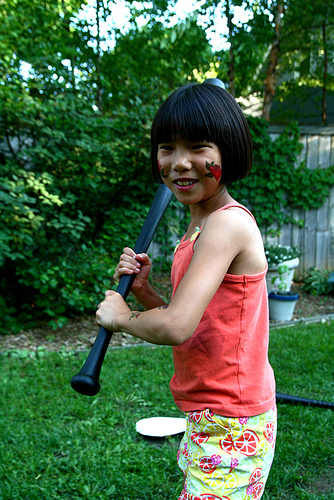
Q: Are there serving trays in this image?
A: No, there are no serving trays.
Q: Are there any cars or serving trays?
A: No, there are no serving trays or cars.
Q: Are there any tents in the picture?
A: No, there are no tents.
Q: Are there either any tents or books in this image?
A: No, there are no tents or books.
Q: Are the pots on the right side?
A: Yes, the pots are on the right of the image.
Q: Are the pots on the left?
A: No, the pots are on the right of the image.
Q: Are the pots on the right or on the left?
A: The pots are on the right of the image.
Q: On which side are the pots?
A: The pots are on the right of the image.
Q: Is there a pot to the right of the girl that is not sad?
A: Yes, there are pots to the right of the girl.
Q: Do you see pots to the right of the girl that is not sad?
A: Yes, there are pots to the right of the girl.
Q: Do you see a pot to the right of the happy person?
A: Yes, there are pots to the right of the girl.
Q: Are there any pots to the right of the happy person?
A: Yes, there are pots to the right of the girl.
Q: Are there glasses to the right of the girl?
A: No, there are pots to the right of the girl.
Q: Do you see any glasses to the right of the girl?
A: No, there are pots to the right of the girl.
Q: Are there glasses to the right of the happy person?
A: No, there are pots to the right of the girl.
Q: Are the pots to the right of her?
A: Yes, the pots are to the right of the girl.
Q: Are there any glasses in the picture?
A: No, there are no glasses.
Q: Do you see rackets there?
A: Yes, there is a racket.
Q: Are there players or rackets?
A: Yes, there is a racket.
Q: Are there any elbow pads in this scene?
A: No, there are no elbow pads.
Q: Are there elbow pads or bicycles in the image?
A: No, there are no elbow pads or bicycles.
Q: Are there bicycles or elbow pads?
A: No, there are no elbow pads or bicycles.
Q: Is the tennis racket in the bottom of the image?
A: Yes, the tennis racket is in the bottom of the image.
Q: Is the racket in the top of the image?
A: No, the racket is in the bottom of the image.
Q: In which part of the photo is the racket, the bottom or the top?
A: The racket is in the bottom of the image.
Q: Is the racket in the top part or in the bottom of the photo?
A: The racket is in the bottom of the image.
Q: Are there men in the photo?
A: No, there are no men.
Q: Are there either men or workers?
A: No, there are no men or workers.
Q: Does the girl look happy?
A: Yes, the girl is happy.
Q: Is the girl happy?
A: Yes, the girl is happy.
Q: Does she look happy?
A: Yes, the girl is happy.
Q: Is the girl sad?
A: No, the girl is happy.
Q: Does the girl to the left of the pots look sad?
A: No, the girl is happy.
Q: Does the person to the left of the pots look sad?
A: No, the girl is happy.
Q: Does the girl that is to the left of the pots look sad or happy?
A: The girl is happy.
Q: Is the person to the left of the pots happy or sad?
A: The girl is happy.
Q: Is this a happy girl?
A: Yes, this is a happy girl.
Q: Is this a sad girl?
A: No, this is a happy girl.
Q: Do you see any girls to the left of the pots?
A: Yes, there is a girl to the left of the pots.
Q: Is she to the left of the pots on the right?
A: Yes, the girl is to the left of the pots.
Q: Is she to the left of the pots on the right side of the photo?
A: Yes, the girl is to the left of the pots.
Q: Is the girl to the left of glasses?
A: No, the girl is to the left of the pots.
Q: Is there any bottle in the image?
A: No, there are no bottles.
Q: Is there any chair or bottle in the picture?
A: No, there are no bottles or chairs.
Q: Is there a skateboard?
A: No, there are no skateboards.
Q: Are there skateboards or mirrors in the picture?
A: No, there are no skateboards or mirrors.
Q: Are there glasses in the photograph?
A: No, there are no glasses.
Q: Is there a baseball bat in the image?
A: Yes, there is a baseball bat.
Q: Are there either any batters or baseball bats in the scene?
A: Yes, there is a baseball bat.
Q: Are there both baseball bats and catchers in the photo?
A: No, there is a baseball bat but no catchers.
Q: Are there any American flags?
A: No, there are no American flags.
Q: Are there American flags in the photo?
A: No, there are no American flags.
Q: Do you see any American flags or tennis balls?
A: No, there are no American flags or tennis balls.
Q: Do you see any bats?
A: Yes, there is a bat.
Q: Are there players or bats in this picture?
A: Yes, there is a bat.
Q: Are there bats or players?
A: Yes, there is a bat.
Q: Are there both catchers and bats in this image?
A: No, there is a bat but no catchers.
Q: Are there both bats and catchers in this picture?
A: No, there is a bat but no catchers.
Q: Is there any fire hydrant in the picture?
A: No, there are no fire hydrants.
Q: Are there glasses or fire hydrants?
A: No, there are no fire hydrants or glasses.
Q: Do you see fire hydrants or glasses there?
A: No, there are no fire hydrants or glasses.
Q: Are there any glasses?
A: No, there are no glasses.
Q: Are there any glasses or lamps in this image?
A: No, there are no glasses or lamps.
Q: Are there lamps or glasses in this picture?
A: No, there are no glasses or lamps.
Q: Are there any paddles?
A: No, there are no paddles.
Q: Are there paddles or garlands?
A: No, there are no paddles or garlands.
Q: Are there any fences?
A: Yes, there is a fence.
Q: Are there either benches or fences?
A: Yes, there is a fence.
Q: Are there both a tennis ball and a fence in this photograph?
A: No, there is a fence but no tennis balls.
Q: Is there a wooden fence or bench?
A: Yes, there is a wood fence.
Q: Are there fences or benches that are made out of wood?
A: Yes, the fence is made of wood.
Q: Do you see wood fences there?
A: Yes, there is a wood fence.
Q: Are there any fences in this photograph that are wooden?
A: Yes, there is a fence that is wooden.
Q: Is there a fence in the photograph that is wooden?
A: Yes, there is a fence that is wooden.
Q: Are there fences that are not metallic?
A: Yes, there is a wooden fence.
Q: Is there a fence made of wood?
A: Yes, there is a fence that is made of wood.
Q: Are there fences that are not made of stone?
A: Yes, there is a fence that is made of wood.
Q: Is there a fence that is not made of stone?
A: Yes, there is a fence that is made of wood.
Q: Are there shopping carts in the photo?
A: No, there are no shopping carts.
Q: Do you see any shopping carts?
A: No, there are no shopping carts.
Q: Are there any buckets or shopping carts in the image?
A: No, there are no shopping carts or buckets.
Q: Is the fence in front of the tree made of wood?
A: Yes, the fence is made of wood.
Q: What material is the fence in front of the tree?
A: The fence is made of wood.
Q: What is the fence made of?
A: The fence is made of wood.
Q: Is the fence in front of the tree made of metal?
A: No, the fence is made of wood.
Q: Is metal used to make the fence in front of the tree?
A: No, the fence is made of wood.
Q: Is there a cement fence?
A: No, there is a fence but it is made of wood.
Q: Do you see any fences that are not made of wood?
A: No, there is a fence but it is made of wood.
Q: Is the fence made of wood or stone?
A: The fence is made of wood.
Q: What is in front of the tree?
A: The fence is in front of the tree.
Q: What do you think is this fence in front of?
A: The fence is in front of the tree.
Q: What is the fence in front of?
A: The fence is in front of the tree.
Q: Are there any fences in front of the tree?
A: Yes, there is a fence in front of the tree.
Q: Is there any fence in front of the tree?
A: Yes, there is a fence in front of the tree.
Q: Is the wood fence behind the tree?
A: No, the fence is in front of the tree.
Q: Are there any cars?
A: No, there are no cars.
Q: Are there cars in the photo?
A: No, there are no cars.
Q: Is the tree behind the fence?
A: Yes, the tree is behind the fence.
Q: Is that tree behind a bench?
A: No, the tree is behind the fence.